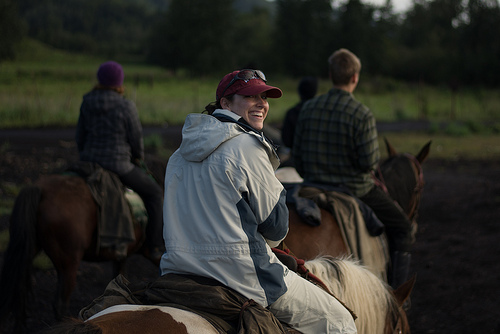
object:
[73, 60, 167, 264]
person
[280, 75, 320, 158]
person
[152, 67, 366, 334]
people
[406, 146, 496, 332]
dirt field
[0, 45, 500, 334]
game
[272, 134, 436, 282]
horse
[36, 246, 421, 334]
horse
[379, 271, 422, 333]
head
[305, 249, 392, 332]
mane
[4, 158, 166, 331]
horse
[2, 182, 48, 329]
horse tail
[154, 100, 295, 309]
jacket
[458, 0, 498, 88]
trees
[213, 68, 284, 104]
cap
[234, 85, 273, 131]
face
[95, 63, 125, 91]
hat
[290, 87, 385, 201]
shirt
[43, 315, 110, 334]
tail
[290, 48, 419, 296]
guy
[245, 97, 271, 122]
smile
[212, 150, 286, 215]
line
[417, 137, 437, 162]
ears